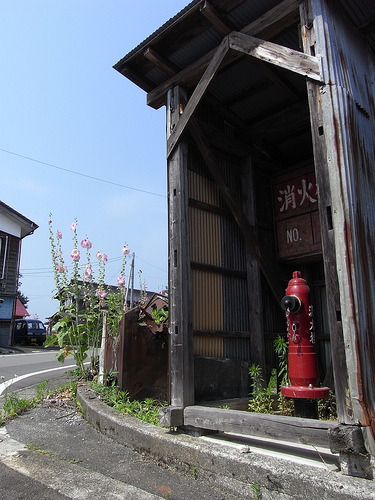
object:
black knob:
[281, 295, 302, 314]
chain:
[286, 307, 297, 342]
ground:
[308, 131, 319, 146]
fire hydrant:
[280, 271, 329, 420]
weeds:
[249, 333, 336, 417]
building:
[112, 1, 375, 480]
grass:
[86, 366, 166, 427]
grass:
[0, 378, 72, 424]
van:
[14, 296, 31, 316]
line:
[0, 434, 164, 499]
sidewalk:
[87, 390, 375, 500]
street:
[6, 349, 52, 392]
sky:
[14, 18, 109, 196]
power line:
[0, 143, 167, 202]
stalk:
[69, 216, 79, 374]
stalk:
[116, 256, 127, 323]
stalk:
[47, 211, 57, 277]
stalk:
[55, 228, 69, 287]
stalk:
[80, 273, 90, 342]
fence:
[117, 305, 170, 405]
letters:
[287, 228, 299, 244]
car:
[13, 319, 46, 346]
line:
[0, 352, 87, 396]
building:
[0, 198, 39, 346]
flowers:
[45, 211, 147, 309]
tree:
[18, 273, 29, 309]